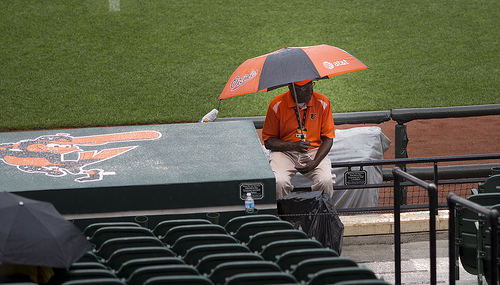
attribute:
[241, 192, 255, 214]
bottle — blue 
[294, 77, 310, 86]
bill — orange 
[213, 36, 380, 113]
umbrella — black, large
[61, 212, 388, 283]
seats — green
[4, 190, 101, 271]
umbrella — black 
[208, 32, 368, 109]
umbrella — orange, black, large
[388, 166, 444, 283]
rail — metal, black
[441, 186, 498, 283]
rail — black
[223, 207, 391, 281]
seats — green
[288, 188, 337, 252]
cart — covered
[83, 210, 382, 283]
seats — empty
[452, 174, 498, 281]
seats — empty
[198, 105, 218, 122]
bottle — empty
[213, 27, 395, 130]
umbrella — black 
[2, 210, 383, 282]
folding chairs — rowed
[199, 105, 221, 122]
bottle — red 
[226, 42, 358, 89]
umbrella — black, orange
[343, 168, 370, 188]
signs — small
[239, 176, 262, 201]
signs — small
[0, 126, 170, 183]
team mascot — black , orange 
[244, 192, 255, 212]
bottle — plastic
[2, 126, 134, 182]
logo — team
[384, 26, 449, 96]
grass — green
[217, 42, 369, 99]
umbrella — black , orange 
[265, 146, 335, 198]
pants — tan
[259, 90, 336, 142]
shirt — orange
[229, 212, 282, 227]
seat — green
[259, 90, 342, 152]
shirt — orange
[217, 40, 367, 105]
umbrella — orange , black 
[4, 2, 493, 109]
grass — green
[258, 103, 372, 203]
ma — holding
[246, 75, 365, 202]
man — sitting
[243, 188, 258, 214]
bottle — water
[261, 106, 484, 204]
warning track — sandy